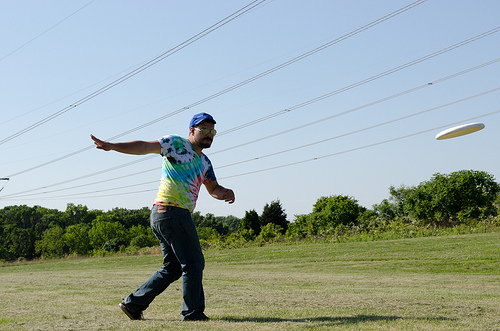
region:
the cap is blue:
[175, 105, 212, 135]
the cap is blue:
[159, 104, 229, 141]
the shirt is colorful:
[133, 114, 235, 246]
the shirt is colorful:
[158, 125, 272, 257]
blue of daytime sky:
[1, 2, 498, 215]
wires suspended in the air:
[6, 1, 495, 201]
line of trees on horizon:
[0, 170, 497, 259]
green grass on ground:
[0, 234, 497, 329]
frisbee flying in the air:
[433, 120, 485, 142]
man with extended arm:
[88, 112, 235, 318]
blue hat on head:
[189, 111, 216, 131]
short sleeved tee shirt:
[156, 136, 214, 208]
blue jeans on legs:
[126, 204, 206, 312]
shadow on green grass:
[216, 314, 446, 329]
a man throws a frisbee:
[25, 63, 487, 302]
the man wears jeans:
[74, 63, 311, 303]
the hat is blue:
[81, 83, 254, 270]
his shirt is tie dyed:
[70, 82, 294, 319]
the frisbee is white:
[403, 89, 478, 178]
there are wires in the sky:
[63, 24, 478, 238]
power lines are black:
[61, 52, 461, 274]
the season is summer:
[57, 46, 491, 327]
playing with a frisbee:
[41, 29, 476, 269]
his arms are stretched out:
[73, 29, 289, 261]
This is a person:
[87, 105, 256, 329]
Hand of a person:
[201, 159, 258, 222]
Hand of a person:
[88, 127, 172, 167]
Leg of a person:
[164, 210, 227, 329]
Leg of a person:
[106, 210, 173, 319]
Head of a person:
[183, 105, 226, 152]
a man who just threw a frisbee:
[57, 77, 349, 319]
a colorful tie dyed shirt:
[123, 125, 224, 240]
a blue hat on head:
[181, 103, 227, 136]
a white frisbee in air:
[437, 107, 480, 153]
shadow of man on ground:
[186, 293, 486, 328]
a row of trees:
[3, 183, 498, 254]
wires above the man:
[16, 20, 497, 246]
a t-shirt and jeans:
[108, 132, 249, 328]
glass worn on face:
[194, 124, 231, 143]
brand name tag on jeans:
[153, 201, 175, 218]